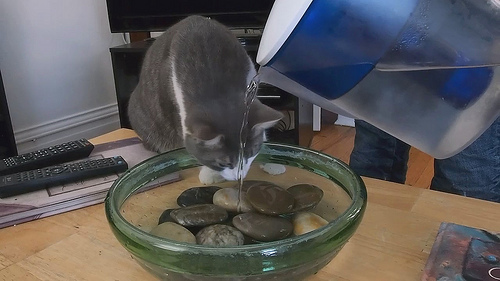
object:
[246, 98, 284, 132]
ear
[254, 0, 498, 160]
pitcher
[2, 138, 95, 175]
remotes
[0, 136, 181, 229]
book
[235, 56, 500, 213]
water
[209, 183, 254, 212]
rock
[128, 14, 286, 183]
cat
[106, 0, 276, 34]
television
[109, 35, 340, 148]
television stand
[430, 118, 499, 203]
legs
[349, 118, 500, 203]
jeans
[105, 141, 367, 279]
bowl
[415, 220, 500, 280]
book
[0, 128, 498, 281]
table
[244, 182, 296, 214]
rock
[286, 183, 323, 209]
rock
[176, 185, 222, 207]
rock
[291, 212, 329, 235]
rock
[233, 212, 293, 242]
rock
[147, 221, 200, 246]
rock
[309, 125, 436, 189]
floor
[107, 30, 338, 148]
stand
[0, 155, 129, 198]
remote controls